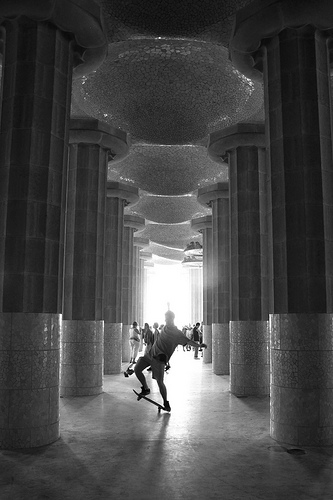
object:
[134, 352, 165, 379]
shorts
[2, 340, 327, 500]
floor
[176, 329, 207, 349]
arm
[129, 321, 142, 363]
woman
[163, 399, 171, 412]
shoe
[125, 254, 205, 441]
light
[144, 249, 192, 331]
outdoor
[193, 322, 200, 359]
person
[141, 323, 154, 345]
person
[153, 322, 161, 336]
person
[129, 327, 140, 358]
cloths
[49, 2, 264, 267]
ceiling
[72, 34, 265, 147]
design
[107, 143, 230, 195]
design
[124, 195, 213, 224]
design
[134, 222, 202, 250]
design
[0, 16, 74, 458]
column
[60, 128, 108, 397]
column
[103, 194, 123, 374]
column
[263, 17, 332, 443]
column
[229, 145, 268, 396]
column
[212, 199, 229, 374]
column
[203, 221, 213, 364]
column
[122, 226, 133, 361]
column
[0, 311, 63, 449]
bottom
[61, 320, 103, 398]
bottom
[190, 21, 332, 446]
columns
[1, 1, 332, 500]
building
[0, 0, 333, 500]
picture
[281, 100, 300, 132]
stone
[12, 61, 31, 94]
stone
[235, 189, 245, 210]
stone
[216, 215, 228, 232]
stone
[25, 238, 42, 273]
stone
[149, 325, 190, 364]
shirt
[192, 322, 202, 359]
woman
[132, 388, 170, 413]
cell phone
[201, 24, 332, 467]
poles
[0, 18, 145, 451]
poles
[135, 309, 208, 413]
man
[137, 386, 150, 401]
shoe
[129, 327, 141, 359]
outfit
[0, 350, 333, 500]
hallway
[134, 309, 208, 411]
skater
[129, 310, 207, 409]
people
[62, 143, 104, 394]
pole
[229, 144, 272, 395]
pole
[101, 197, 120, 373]
pole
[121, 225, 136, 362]
pole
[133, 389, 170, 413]
skateboard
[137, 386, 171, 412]
shoes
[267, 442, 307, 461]
no objects